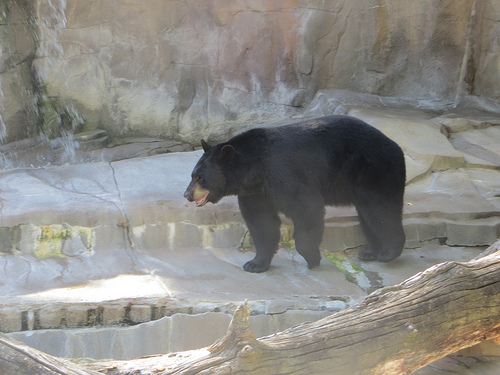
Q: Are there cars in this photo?
A: No, there are no cars.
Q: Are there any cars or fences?
A: No, there are no cars or fences.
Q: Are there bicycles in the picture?
A: No, there are no bicycles.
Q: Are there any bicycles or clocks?
A: No, there are no bicycles or clocks.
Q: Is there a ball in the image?
A: No, there are no balls.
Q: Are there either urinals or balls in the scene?
A: No, there are no balls or urinals.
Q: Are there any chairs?
A: No, there are no chairs.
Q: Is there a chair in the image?
A: No, there are no chairs.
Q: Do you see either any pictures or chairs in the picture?
A: No, there are no chairs or pictures.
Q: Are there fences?
A: No, there are no fences.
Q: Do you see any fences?
A: No, there are no fences.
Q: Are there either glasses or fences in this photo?
A: No, there are no fences or glasses.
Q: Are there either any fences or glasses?
A: No, there are no fences or glasses.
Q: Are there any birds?
A: No, there are no birds.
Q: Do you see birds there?
A: No, there are no birds.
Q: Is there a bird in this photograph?
A: No, there are no birds.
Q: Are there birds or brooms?
A: No, there are no birds or brooms.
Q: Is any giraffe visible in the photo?
A: No, there are no giraffes.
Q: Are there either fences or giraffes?
A: No, there are no giraffes or fences.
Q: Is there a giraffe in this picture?
A: No, there are no giraffes.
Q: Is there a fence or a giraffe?
A: No, there are no giraffes or fences.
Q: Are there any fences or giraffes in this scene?
A: No, there are no giraffes or fences.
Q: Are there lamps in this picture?
A: No, there are no lamps.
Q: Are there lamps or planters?
A: No, there are no lamps or planters.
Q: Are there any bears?
A: Yes, there is a bear.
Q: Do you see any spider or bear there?
A: Yes, there is a bear.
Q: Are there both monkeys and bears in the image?
A: No, there is a bear but no monkeys.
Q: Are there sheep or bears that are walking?
A: Yes, the bear is walking.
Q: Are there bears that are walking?
A: Yes, there is a bear that is walking.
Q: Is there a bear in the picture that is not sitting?
A: Yes, there is a bear that is walking.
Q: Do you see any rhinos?
A: No, there are no rhinos.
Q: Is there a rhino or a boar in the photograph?
A: No, there are no rhinos or boars.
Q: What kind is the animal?
A: The animal is a bear.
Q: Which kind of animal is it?
A: The animal is a bear.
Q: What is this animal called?
A: This is a bear.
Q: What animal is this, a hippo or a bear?
A: This is a bear.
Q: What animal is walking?
A: The animal is a bear.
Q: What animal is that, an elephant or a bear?
A: That is a bear.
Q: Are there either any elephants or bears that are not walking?
A: No, there is a bear but it is walking.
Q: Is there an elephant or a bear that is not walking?
A: No, there is a bear but it is walking.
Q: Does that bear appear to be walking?
A: Yes, the bear is walking.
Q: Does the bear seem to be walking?
A: Yes, the bear is walking.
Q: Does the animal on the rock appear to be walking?
A: Yes, the bear is walking.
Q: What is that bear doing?
A: The bear is walking.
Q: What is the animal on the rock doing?
A: The bear is walking.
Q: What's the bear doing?
A: The bear is walking.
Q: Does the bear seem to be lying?
A: No, the bear is walking.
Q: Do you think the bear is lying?
A: No, the bear is walking.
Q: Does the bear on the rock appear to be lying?
A: No, the bear is walking.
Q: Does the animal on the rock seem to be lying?
A: No, the bear is walking.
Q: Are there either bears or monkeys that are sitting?
A: No, there is a bear but it is walking.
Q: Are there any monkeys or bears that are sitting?
A: No, there is a bear but it is walking.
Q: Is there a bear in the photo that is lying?
A: No, there is a bear but it is walking.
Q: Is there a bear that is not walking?
A: No, there is a bear but it is walking.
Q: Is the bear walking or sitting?
A: The bear is walking.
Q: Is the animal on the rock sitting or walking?
A: The bear is walking.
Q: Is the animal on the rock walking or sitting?
A: The bear is walking.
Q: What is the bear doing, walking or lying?
A: The bear is walking.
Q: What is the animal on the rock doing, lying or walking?
A: The bear is walking.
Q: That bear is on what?
A: The bear is on the rock.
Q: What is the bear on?
A: The bear is on the rock.